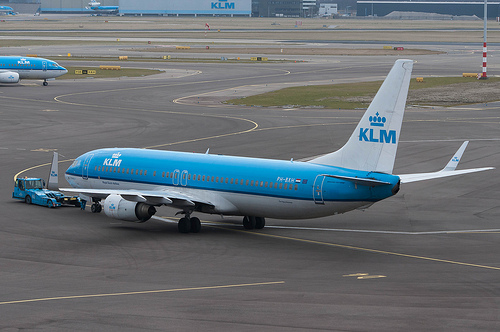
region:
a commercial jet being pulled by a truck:
[11, 42, 496, 265]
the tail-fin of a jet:
[344, 56, 424, 164]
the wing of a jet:
[42, 147, 214, 210]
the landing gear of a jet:
[173, 208, 203, 235]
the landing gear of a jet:
[239, 213, 267, 233]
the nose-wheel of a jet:
[83, 193, 101, 215]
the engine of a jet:
[101, 193, 156, 225]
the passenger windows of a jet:
[88, 162, 299, 197]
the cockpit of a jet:
[68, 156, 80, 167]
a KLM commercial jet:
[66, 54, 498, 251]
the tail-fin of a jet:
[338, 40, 418, 167]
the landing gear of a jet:
[172, 203, 207, 234]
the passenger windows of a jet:
[93, 163, 208, 185]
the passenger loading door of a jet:
[82, 152, 92, 181]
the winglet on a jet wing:
[36, 149, 67, 191]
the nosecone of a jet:
[57, 64, 68, 78]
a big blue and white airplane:
[31, 66, 441, 241]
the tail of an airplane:
[349, 66, 419, 177]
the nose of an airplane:
[48, 145, 105, 190]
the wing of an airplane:
[48, 167, 163, 209]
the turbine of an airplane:
[81, 186, 164, 228]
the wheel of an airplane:
[166, 205, 282, 239]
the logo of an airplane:
[364, 104, 413, 159]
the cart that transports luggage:
[3, 156, 69, 218]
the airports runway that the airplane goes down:
[123, 250, 217, 319]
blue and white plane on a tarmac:
[60, 56, 493, 238]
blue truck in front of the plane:
[10, 150, 85, 210]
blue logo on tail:
[365, 107, 385, 127]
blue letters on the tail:
[355, 125, 391, 142]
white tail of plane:
[305, 55, 415, 170]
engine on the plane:
[101, 191, 151, 221]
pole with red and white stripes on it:
[477, 0, 487, 77]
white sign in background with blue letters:
[120, 0, 250, 15]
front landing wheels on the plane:
[90, 202, 101, 212]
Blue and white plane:
[55, 55, 495, 228]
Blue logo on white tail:
[355, 109, 398, 146]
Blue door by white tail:
[308, 172, 328, 204]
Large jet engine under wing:
[103, 194, 155, 223]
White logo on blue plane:
[102, 149, 124, 169]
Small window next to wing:
[188, 173, 196, 180]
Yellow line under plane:
[222, 222, 498, 272]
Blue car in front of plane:
[10, 173, 70, 206]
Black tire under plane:
[176, 213, 191, 232]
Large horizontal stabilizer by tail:
[316, 171, 395, 187]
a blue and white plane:
[0, 48, 85, 88]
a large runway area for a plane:
[7, 10, 464, 328]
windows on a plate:
[93, 157, 323, 195]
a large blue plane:
[15, 111, 436, 231]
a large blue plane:
[46, 55, 466, 255]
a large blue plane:
[35, 51, 473, 228]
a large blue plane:
[0, 49, 74, 96]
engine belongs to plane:
[103, 192, 157, 222]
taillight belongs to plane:
[314, 52, 416, 180]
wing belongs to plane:
[54, 184, 213, 221]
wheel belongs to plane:
[189, 214, 201, 231]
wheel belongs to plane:
[175, 216, 188, 235]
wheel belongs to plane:
[253, 215, 265, 229]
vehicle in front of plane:
[12, 174, 79, 211]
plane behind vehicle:
[62, 60, 494, 233]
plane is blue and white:
[0, 55, 71, 87]